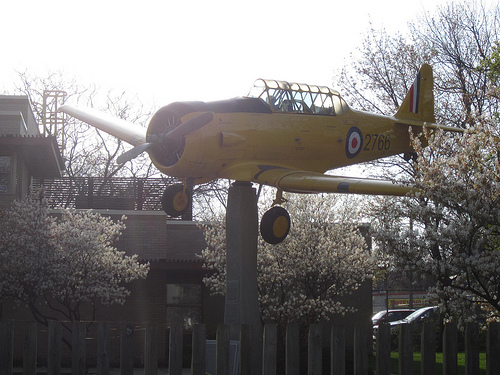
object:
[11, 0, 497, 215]
sky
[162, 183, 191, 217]
wheel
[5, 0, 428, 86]
clouds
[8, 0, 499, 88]
sky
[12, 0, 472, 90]
clouds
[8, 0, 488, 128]
sky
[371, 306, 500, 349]
car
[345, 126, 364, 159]
circle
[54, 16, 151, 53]
clouds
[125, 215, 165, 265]
wall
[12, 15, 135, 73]
clouds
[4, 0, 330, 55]
sky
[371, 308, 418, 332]
car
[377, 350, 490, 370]
lawn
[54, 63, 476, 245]
airplane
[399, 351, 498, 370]
grass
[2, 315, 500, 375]
fence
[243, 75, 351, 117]
frame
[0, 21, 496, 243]
sky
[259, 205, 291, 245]
landing gear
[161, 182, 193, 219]
landing gear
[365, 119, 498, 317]
blossoms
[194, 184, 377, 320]
blossoms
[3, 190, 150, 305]
blossoms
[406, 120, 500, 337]
trees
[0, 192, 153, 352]
trees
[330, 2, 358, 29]
white clouds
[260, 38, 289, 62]
white clouds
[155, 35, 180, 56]
white clouds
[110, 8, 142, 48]
white clouds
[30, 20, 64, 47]
white clouds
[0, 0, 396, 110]
sky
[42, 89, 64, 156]
metal frame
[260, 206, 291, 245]
wheel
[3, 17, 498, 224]
sky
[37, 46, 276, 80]
clouds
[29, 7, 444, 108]
sky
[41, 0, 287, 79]
light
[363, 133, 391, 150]
numbers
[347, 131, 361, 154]
rings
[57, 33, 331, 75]
clouds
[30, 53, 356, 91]
sky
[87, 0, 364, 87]
clouds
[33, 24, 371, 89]
clouds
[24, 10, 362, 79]
clouds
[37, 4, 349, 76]
clouds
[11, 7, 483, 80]
sky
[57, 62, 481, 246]
plane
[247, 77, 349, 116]
cockpit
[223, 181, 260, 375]
post